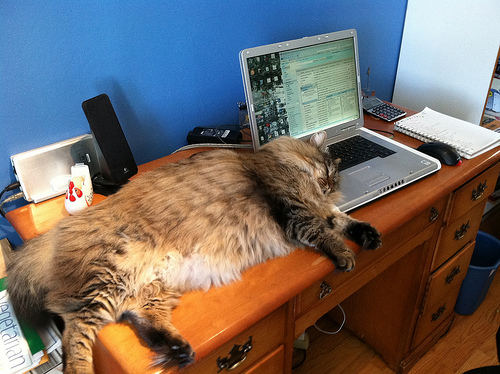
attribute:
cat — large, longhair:
[1, 126, 391, 370]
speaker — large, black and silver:
[74, 90, 144, 187]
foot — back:
[161, 327, 241, 361]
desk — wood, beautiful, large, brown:
[6, 98, 498, 371]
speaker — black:
[79, 90, 141, 197]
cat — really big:
[31, 117, 364, 360]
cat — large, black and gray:
[43, 72, 368, 360]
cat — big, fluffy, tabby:
[7, 119, 409, 337]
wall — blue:
[0, 1, 407, 251]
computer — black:
[233, 25, 443, 219]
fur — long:
[131, 190, 242, 280]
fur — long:
[156, 350, 175, 366]